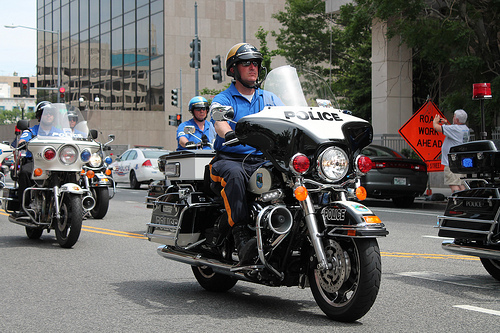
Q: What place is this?
A: It is a road.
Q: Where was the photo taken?
A: It was taken at the road.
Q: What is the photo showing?
A: It is showing a road.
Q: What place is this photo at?
A: It is at the road.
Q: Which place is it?
A: It is a road.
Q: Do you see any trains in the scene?
A: No, there are no trains.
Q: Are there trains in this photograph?
A: No, there are no trains.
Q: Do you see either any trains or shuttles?
A: No, there are no trains or shuttles.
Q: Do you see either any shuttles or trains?
A: No, there are no trains or shuttles.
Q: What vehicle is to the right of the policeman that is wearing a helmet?
A: The vehicle is a car.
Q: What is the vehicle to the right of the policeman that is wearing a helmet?
A: The vehicle is a car.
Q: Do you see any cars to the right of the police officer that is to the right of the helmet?
A: Yes, there is a car to the right of the police officer.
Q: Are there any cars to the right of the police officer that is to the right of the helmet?
A: Yes, there is a car to the right of the police officer.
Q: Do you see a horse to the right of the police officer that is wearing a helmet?
A: No, there is a car to the right of the policeman.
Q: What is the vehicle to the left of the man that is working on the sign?
A: The vehicle is a car.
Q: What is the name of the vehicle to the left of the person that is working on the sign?
A: The vehicle is a car.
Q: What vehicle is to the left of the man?
A: The vehicle is a car.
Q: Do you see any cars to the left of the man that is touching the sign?
A: Yes, there is a car to the left of the man.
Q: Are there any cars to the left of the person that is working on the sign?
A: Yes, there is a car to the left of the man.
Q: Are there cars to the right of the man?
A: No, the car is to the left of the man.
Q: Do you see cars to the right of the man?
A: No, the car is to the left of the man.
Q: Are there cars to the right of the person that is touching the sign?
A: No, the car is to the left of the man.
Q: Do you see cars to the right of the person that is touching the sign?
A: No, the car is to the left of the man.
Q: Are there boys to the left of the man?
A: No, there is a car to the left of the man.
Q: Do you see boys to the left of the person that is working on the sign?
A: No, there is a car to the left of the man.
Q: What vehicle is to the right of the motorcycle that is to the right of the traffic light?
A: The vehicle is a car.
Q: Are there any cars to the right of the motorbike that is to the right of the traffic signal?
A: Yes, there is a car to the right of the motorbike.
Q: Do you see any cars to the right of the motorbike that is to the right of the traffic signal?
A: Yes, there is a car to the right of the motorbike.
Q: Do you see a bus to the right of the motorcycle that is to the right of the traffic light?
A: No, there is a car to the right of the motorcycle.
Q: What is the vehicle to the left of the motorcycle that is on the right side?
A: The vehicle is a car.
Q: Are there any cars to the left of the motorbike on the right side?
A: Yes, there is a car to the left of the motorcycle.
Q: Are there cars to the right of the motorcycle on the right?
A: No, the car is to the left of the motorcycle.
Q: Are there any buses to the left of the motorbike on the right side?
A: No, there is a car to the left of the motorcycle.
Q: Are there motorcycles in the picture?
A: Yes, there is a motorcycle.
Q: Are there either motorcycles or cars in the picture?
A: Yes, there is a motorcycle.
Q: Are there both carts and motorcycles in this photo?
A: No, there is a motorcycle but no carts.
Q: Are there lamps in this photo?
A: No, there are no lamps.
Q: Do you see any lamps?
A: No, there are no lamps.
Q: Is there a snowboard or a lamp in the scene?
A: No, there are no lamps or snowboards.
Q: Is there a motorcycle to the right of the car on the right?
A: Yes, there is a motorcycle to the right of the car.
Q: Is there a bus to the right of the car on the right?
A: No, there is a motorcycle to the right of the car.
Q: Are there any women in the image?
A: No, there are no women.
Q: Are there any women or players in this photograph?
A: No, there are no women or players.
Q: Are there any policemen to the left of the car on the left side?
A: Yes, there is a policeman to the left of the car.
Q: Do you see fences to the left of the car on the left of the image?
A: No, there is a policeman to the left of the car.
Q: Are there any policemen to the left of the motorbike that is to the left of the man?
A: Yes, there is a policeman to the left of the motorcycle.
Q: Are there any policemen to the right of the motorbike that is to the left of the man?
A: No, the policeman is to the left of the motorcycle.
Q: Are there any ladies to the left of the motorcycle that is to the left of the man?
A: No, there is a policeman to the left of the motorcycle.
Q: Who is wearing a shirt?
A: The police officer is wearing a shirt.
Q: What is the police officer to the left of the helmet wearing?
A: The police officer is wearing a shirt.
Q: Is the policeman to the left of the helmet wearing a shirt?
A: Yes, the police officer is wearing a shirt.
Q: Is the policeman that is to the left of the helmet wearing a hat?
A: No, the policeman is wearing a shirt.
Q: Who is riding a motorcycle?
A: The policeman is riding a motorcycle.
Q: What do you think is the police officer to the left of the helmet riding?
A: The police officer is riding a motorcycle.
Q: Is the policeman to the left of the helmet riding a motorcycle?
A: Yes, the police officer is riding a motorcycle.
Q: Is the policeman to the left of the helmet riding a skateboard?
A: No, the police officer is riding a motorcycle.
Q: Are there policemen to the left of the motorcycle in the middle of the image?
A: Yes, there is a policeman to the left of the motorcycle.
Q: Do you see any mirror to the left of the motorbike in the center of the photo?
A: No, there is a policeman to the left of the motorcycle.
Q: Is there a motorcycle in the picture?
A: Yes, there is a motorcycle.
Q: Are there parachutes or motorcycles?
A: Yes, there is a motorcycle.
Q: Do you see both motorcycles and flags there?
A: No, there is a motorcycle but no flags.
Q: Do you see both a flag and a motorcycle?
A: No, there is a motorcycle but no flags.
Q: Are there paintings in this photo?
A: No, there are no paintings.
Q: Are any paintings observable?
A: No, there are no paintings.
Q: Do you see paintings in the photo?
A: No, there are no paintings.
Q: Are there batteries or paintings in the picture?
A: No, there are no paintings or batteries.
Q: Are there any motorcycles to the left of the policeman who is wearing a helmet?
A: Yes, there is a motorcycle to the left of the police officer.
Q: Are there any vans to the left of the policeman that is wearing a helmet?
A: No, there is a motorcycle to the left of the police officer.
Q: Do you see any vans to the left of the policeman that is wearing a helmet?
A: No, there is a motorcycle to the left of the police officer.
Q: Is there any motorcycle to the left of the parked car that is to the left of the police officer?
A: Yes, there is a motorcycle to the left of the car.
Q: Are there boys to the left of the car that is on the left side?
A: No, there is a motorcycle to the left of the car.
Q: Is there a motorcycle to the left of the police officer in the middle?
A: Yes, there is a motorcycle to the left of the police officer.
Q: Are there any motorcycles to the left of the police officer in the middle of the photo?
A: Yes, there is a motorcycle to the left of the police officer.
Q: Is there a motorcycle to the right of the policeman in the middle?
A: No, the motorcycle is to the left of the police officer.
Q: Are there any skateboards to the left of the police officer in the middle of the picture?
A: No, there is a motorcycle to the left of the police officer.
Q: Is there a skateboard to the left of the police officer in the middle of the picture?
A: No, there is a motorcycle to the left of the police officer.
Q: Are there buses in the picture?
A: No, there are no buses.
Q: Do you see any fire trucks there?
A: No, there are no fire trucks.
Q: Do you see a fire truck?
A: No, there are no fire trucks.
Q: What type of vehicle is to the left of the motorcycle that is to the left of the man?
A: The vehicle is a car.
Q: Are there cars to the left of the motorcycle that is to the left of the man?
A: Yes, there is a car to the left of the motorcycle.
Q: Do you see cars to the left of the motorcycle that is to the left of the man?
A: Yes, there is a car to the left of the motorcycle.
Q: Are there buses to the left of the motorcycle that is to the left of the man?
A: No, there is a car to the left of the motorcycle.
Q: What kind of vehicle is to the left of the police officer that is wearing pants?
A: The vehicle is a car.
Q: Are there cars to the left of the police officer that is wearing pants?
A: Yes, there is a car to the left of the policeman.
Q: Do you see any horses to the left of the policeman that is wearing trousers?
A: No, there is a car to the left of the police officer.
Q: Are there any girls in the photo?
A: No, there are no girls.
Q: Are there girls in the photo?
A: No, there are no girls.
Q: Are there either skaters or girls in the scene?
A: No, there are no girls or skaters.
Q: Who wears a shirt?
A: The policeman wears a shirt.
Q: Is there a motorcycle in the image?
A: Yes, there is a motorcycle.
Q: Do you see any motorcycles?
A: Yes, there is a motorcycle.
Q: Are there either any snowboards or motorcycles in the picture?
A: Yes, there is a motorcycle.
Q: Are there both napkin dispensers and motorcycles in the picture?
A: No, there is a motorcycle but no napkin dispensers.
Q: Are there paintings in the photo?
A: No, there are no paintings.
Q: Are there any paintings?
A: No, there are no paintings.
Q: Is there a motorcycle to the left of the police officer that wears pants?
A: Yes, there is a motorcycle to the left of the policeman.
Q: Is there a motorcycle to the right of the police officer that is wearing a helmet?
A: No, the motorcycle is to the left of the policeman.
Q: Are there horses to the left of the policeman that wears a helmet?
A: No, there is a motorcycle to the left of the policeman.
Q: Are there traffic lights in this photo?
A: Yes, there is a traffic light.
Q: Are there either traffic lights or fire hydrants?
A: Yes, there is a traffic light.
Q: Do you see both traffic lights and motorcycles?
A: Yes, there are both a traffic light and a motorcycle.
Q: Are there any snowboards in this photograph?
A: No, there are no snowboards.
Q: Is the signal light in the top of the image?
A: Yes, the signal light is in the top of the image.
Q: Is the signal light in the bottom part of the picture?
A: No, the signal light is in the top of the image.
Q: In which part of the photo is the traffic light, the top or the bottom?
A: The traffic light is in the top of the image.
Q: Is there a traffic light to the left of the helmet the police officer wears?
A: Yes, there is a traffic light to the left of the helmet.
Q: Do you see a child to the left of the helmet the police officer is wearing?
A: No, there is a traffic light to the left of the helmet.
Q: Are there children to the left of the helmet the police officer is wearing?
A: No, there is a traffic light to the left of the helmet.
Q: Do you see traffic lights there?
A: Yes, there is a traffic light.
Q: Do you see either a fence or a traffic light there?
A: Yes, there is a traffic light.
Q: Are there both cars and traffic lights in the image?
A: Yes, there are both a traffic light and a car.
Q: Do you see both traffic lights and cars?
A: Yes, there are both a traffic light and a car.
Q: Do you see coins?
A: No, there are no coins.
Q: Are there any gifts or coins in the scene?
A: No, there are no coins or gifts.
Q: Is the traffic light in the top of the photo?
A: Yes, the traffic light is in the top of the image.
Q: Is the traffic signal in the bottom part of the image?
A: No, the traffic signal is in the top of the image.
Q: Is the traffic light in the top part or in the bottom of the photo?
A: The traffic light is in the top of the image.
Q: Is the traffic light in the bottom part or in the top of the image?
A: The traffic light is in the top of the image.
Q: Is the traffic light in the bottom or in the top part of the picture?
A: The traffic light is in the top of the image.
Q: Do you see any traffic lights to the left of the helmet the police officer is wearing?
A: Yes, there is a traffic light to the left of the helmet.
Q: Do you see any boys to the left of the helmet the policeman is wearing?
A: No, there is a traffic light to the left of the helmet.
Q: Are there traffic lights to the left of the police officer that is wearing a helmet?
A: Yes, there is a traffic light to the left of the police officer.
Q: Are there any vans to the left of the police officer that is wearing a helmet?
A: No, there is a traffic light to the left of the police officer.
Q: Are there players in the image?
A: No, there are no players.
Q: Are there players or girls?
A: No, there are no players or girls.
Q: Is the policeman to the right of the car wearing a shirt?
A: Yes, the policeman is wearing a shirt.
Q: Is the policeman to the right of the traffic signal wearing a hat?
A: No, the police officer is wearing a shirt.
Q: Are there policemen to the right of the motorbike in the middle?
A: Yes, there is a policeman to the right of the motorbike.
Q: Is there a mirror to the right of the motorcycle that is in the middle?
A: No, there is a policeman to the right of the motorbike.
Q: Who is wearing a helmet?
A: The police officer is wearing a helmet.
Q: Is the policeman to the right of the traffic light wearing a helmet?
A: Yes, the policeman is wearing a helmet.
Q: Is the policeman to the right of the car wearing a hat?
A: No, the police officer is wearing a helmet.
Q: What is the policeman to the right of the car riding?
A: The police officer is riding a motorcycle.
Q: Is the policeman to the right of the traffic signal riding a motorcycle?
A: Yes, the policeman is riding a motorcycle.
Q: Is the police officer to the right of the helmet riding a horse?
A: No, the policeman is riding a motorcycle.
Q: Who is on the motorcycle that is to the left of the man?
A: The policeman is on the motorbike.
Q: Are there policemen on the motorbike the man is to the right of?
A: Yes, there is a policeman on the motorbike.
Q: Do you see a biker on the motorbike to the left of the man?
A: No, there is a policeman on the motorbike.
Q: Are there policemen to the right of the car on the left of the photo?
A: Yes, there is a policeman to the right of the car.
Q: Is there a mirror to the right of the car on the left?
A: No, there is a policeman to the right of the car.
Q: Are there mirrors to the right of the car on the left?
A: No, there is a policeman to the right of the car.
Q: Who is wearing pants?
A: The police officer is wearing pants.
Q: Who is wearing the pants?
A: The police officer is wearing pants.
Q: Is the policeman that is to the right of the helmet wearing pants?
A: Yes, the policeman is wearing pants.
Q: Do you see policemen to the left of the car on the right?
A: Yes, there is a policeman to the left of the car.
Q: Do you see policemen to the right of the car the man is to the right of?
A: No, the policeman is to the left of the car.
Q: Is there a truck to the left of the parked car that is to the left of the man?
A: No, there is a policeman to the left of the car.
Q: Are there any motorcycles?
A: Yes, there is a motorcycle.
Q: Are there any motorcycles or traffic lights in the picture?
A: Yes, there is a motorcycle.